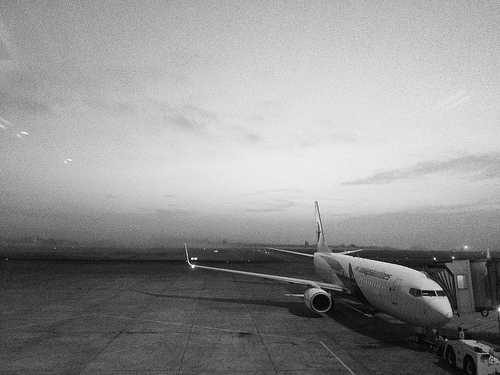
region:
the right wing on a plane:
[181, 242, 345, 315]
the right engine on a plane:
[304, 285, 334, 313]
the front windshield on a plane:
[409, 284, 444, 299]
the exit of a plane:
[430, 260, 493, 312]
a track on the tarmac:
[440, 333, 495, 373]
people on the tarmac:
[431, 325, 466, 356]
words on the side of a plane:
[352, 263, 393, 283]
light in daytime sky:
[2, 0, 498, 242]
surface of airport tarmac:
[2, 260, 499, 374]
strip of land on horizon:
[0, 241, 497, 258]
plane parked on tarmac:
[182, 200, 454, 344]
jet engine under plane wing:
[184, 243, 343, 312]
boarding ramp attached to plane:
[428, 257, 498, 317]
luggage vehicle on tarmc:
[443, 336, 499, 373]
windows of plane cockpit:
[408, 286, 446, 298]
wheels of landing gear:
[413, 329, 428, 344]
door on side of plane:
[390, 277, 400, 304]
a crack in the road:
[82, 330, 129, 372]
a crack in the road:
[88, 281, 122, 313]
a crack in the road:
[123, 271, 156, 293]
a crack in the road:
[155, 268, 180, 292]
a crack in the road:
[131, 296, 167, 321]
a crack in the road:
[168, 336, 209, 368]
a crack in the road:
[192, 275, 226, 306]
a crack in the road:
[241, 302, 262, 327]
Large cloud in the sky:
[358, 154, 406, 203]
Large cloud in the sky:
[383, 200, 474, 225]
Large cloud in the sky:
[85, 81, 195, 137]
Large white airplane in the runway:
[278, 202, 451, 366]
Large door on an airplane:
[383, 269, 411, 308]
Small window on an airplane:
[429, 281, 446, 300]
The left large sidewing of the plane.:
[182, 244, 344, 300]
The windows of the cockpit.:
[407, 288, 445, 298]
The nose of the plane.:
[442, 311, 452, 321]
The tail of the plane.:
[313, 201, 325, 251]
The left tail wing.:
[263, 244, 313, 258]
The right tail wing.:
[336, 244, 364, 253]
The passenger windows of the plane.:
[317, 264, 391, 294]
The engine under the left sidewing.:
[295, 282, 330, 316]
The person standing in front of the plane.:
[454, 324, 464, 339]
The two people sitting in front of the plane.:
[430, 330, 448, 345]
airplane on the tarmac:
[170, 212, 465, 338]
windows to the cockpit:
[407, 287, 444, 300]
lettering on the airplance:
[353, 257, 390, 283]